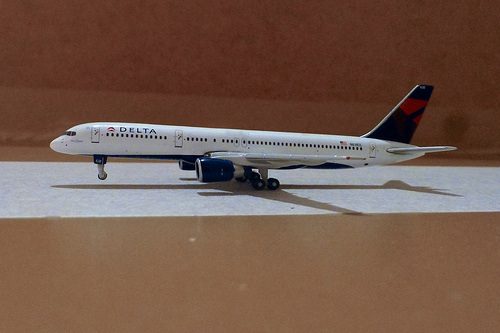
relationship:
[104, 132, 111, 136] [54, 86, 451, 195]
window on model plane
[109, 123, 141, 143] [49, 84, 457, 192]
window on airplanes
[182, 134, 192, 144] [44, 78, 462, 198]
window on plane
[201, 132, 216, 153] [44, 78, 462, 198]
window on plane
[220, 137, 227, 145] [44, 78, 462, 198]
window on plane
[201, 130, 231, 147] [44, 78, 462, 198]
window on plane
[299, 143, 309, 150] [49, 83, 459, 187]
window on model plane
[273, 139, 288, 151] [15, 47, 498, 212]
window on plane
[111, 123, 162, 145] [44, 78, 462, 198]
writing on plane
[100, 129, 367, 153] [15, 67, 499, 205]
windows on plane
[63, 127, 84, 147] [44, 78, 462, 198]
windows on plane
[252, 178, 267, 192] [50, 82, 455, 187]
wheel on plane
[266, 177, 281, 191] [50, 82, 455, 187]
wheel on plane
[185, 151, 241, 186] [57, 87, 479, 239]
engine on plane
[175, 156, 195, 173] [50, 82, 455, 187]
right engine on plane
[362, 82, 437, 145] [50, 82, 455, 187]
tail of plane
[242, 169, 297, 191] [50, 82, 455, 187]
wheels in middle of plane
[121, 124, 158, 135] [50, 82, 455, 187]
word on side of plane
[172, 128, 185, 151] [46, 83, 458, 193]
door on airplane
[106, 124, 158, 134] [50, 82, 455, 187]
delta logo painted on plane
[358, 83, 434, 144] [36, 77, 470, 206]
tail on airplane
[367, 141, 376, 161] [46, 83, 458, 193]
exit door on airplane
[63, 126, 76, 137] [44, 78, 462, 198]
windows of plane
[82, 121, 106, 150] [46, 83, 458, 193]
exit door on airplane